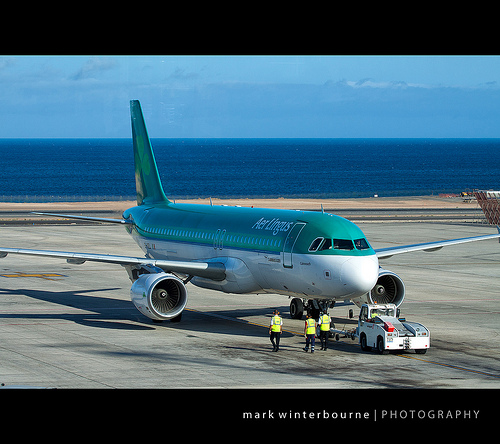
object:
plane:
[0, 100, 500, 324]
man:
[268, 309, 284, 353]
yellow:
[272, 316, 282, 333]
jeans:
[269, 332, 281, 351]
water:
[0, 139, 497, 199]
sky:
[0, 50, 497, 136]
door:
[281, 221, 302, 270]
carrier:
[356, 302, 430, 354]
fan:
[133, 269, 189, 326]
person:
[241, 406, 374, 423]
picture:
[6, 5, 496, 444]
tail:
[130, 98, 174, 205]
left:
[356, 268, 407, 313]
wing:
[0, 240, 211, 279]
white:
[251, 214, 293, 236]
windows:
[132, 221, 282, 249]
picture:
[233, 406, 481, 425]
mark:
[242, 410, 277, 423]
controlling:
[266, 316, 334, 340]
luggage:
[356, 310, 430, 356]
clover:
[135, 171, 148, 195]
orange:
[271, 315, 283, 333]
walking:
[269, 329, 329, 352]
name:
[251, 215, 292, 237]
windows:
[308, 234, 371, 252]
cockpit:
[307, 231, 377, 258]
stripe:
[139, 231, 288, 262]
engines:
[128, 266, 191, 319]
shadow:
[0, 288, 354, 340]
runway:
[0, 212, 497, 388]